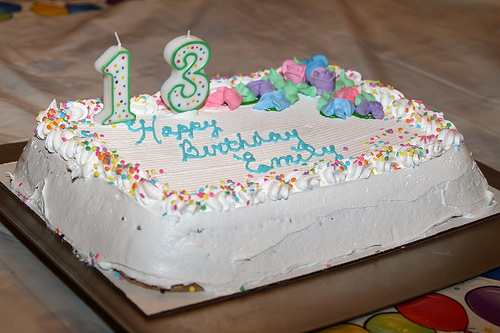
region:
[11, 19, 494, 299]
cake for a birthday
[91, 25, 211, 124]
the number 13 on the cake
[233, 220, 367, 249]
frosting on the cake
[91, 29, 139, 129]
a number one candle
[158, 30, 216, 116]
a number 3 candle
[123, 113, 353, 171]
message written on the cake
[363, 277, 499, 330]
picture of balloons on table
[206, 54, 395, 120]
decorative roses on cake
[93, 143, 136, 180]
sprinkles on the cake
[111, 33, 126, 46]
wicker on the candle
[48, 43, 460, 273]
cake in the photo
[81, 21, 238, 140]
number thirteen on cake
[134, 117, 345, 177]
blue frosting on cake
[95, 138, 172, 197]
sprinkles on the cake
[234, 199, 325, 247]
white frosting on cake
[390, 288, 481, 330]
red balloon picture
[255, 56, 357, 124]
flowers on the cake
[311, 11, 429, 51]
table next to the cake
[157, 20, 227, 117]
candle on the cake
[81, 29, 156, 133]
number on the cake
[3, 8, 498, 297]
Colorful birthday cake.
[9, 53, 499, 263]
Rectangular birthday cake with white icing.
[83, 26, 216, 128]
Number 13 candles.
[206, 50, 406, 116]
Colorful flowers made of icing.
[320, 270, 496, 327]
Balloon tablecloth under a birthday cake.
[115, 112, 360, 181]
Blue lettering on a white cake.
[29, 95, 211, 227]
Colorful sprinkles on the sides of a cake.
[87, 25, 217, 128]
Green and white candles with polka dots.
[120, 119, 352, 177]
Happy Birthday Emily on a birthday cake.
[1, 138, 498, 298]
Rectangular cake pan on a table.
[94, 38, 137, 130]
"1" candle on cake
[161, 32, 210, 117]
"3" candle on cake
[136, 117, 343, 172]
writing on cake top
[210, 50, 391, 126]
icing flowers on cake top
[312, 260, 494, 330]
balloons on tablecloth in bottom right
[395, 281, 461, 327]
red balloon on tablecloth in bottom right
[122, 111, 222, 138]
word "happy" on cake top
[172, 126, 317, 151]
word "birthday" on cake top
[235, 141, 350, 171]
word "Emily" on cake top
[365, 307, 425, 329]
yellow balloon on tablecloth in bottom right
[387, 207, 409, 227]
part of a cake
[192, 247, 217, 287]
edge of a cake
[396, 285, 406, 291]
part of a plate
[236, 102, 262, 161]
part of a cream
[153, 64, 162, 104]
part of a candle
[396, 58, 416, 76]
part of a surface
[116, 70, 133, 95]
part of a number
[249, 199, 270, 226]
edge of a cake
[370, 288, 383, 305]
part of a surface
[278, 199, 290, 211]
part of a cream